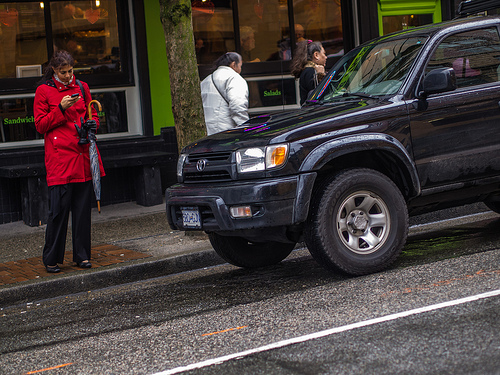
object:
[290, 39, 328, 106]
woman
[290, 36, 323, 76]
hair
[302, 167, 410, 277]
tire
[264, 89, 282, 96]
sign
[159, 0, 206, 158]
tree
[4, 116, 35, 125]
letters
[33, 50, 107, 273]
people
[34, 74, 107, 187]
jacket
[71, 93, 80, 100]
phone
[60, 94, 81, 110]
hand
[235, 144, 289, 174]
left headlight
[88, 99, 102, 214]
elephant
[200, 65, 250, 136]
coat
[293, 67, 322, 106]
coat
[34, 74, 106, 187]
shirt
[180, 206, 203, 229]
sign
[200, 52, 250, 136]
woman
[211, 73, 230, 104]
purse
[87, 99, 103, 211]
umbrella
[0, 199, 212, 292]
sidewalk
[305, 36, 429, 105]
windshield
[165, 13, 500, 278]
car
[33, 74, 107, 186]
coat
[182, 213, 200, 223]
letter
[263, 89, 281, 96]
letter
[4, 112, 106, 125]
sign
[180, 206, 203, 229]
license plate